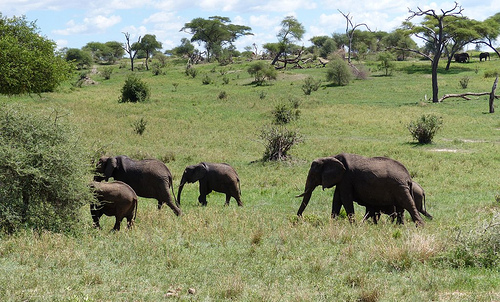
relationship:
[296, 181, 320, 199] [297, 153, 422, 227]
tusk on elephant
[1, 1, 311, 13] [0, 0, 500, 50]
clouds in sky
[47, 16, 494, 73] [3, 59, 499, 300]
trees on grass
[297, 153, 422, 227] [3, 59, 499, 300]
elephant on grass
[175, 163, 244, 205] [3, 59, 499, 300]
baby elephant on grass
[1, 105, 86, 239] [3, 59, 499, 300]
bush on grass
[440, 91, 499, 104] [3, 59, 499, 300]
branch on grass